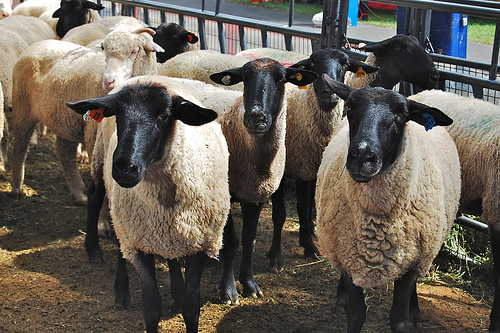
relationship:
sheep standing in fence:
[0, 0, 499, 333] [95, 0, 499, 107]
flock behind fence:
[0, 0, 498, 330] [89, 0, 499, 106]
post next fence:
[394, 2, 466, 95] [117, 0, 495, 90]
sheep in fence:
[0, 0, 500, 333] [95, 0, 499, 107]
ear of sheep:
[62, 87, 118, 124] [0, 0, 500, 333]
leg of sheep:
[135, 250, 170, 331] [0, 0, 500, 333]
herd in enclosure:
[4, 0, 496, 330] [2, 3, 496, 328]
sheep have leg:
[0, 0, 499, 333] [340, 276, 368, 328]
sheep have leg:
[0, 0, 500, 333] [385, 275, 415, 326]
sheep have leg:
[158, 42, 315, 299] [294, 179, 319, 257]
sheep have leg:
[0, 0, 500, 333] [265, 193, 286, 264]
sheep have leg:
[0, 0, 500, 333] [482, 226, 496, 330]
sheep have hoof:
[0, 0, 499, 333] [82, 240, 107, 267]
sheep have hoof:
[0, 0, 500, 333] [5, 167, 26, 195]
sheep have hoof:
[158, 42, 315, 299] [65, 186, 92, 207]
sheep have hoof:
[0, 0, 500, 333] [241, 275, 269, 302]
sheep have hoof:
[0, 0, 500, 333] [217, 282, 241, 307]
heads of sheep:
[77, 49, 438, 188] [298, 67, 466, 327]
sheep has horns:
[5, 19, 169, 214] [108, 18, 160, 38]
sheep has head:
[0, 0, 500, 333] [313, 68, 454, 183]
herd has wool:
[4, 0, 496, 330] [101, 83, 228, 271]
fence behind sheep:
[112, 0, 488, 112] [0, 0, 499, 333]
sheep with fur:
[0, 0, 500, 333] [19, 30, 161, 136]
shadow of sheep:
[10, 234, 214, 324] [122, 81, 434, 229]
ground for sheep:
[7, 244, 89, 307] [0, 0, 499, 333]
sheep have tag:
[0, 0, 500, 333] [81, 100, 108, 123]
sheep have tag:
[0, 0, 499, 333] [220, 72, 232, 88]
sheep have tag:
[0, 0, 500, 333] [290, 70, 314, 92]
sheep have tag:
[0, 0, 500, 333] [417, 109, 439, 131]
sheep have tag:
[0, 0, 500, 333] [353, 62, 366, 79]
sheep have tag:
[0, 0, 500, 333] [181, 26, 200, 42]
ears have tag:
[209, 64, 250, 94] [81, 100, 108, 123]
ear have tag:
[65, 94, 114, 118] [220, 72, 232, 88]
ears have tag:
[290, 57, 313, 100] [290, 70, 314, 92]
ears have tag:
[349, 52, 371, 79] [417, 109, 439, 131]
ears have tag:
[178, 17, 209, 50] [353, 62, 366, 79]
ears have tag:
[161, 86, 219, 122] [181, 26, 200, 42]